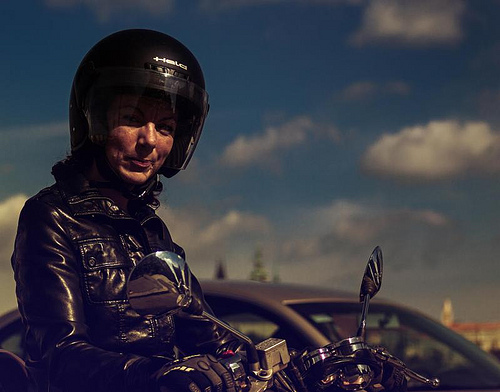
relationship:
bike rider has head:
[10, 28, 240, 392] [70, 29, 205, 188]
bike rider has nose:
[10, 28, 240, 392] [135, 111, 162, 151]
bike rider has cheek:
[10, 28, 240, 392] [95, 120, 147, 148]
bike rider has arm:
[10, 28, 240, 392] [8, 198, 141, 380]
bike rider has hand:
[10, 28, 240, 392] [144, 343, 242, 391]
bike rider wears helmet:
[10, 28, 240, 392] [71, 26, 209, 180]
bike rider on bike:
[10, 28, 240, 392] [4, 240, 441, 389]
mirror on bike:
[123, 249, 195, 318] [4, 240, 441, 389]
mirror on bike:
[358, 245, 384, 301] [4, 240, 441, 389]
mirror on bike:
[126, 246, 382, 316] [4, 240, 441, 389]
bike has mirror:
[0, 246, 439, 392] [351, 236, 391, 302]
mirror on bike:
[125, 250, 195, 319] [1, 226, 449, 383]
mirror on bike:
[358, 245, 384, 301] [1, 226, 449, 383]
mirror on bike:
[339, 247, 399, 313] [2, 340, 449, 390]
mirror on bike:
[358, 245, 384, 301] [146, 286, 406, 390]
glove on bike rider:
[159, 349, 238, 390] [8, 23, 255, 389]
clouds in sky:
[341, 0, 475, 56] [0, 0, 499, 321]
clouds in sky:
[357, 112, 499, 188] [0, 0, 499, 321]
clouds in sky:
[209, 108, 346, 175] [0, 0, 499, 321]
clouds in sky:
[154, 195, 499, 278] [0, 0, 499, 321]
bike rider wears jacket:
[10, 28, 240, 392] [5, 177, 206, 384]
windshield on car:
[301, 295, 497, 377] [1, 267, 498, 388]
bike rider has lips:
[10, 28, 240, 392] [128, 154, 156, 168]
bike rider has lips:
[10, 28, 240, 392] [120, 154, 158, 172]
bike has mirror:
[4, 240, 441, 389] [123, 246, 261, 371]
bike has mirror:
[4, 240, 441, 389] [354, 240, 389, 344]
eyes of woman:
[113, 112, 175, 135] [14, 30, 224, 360]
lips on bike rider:
[125, 153, 153, 170] [10, 28, 240, 392]